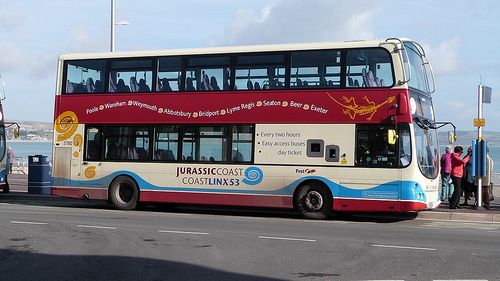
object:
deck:
[63, 59, 396, 91]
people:
[450, 146, 472, 209]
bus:
[0, 75, 14, 191]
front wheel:
[292, 180, 337, 219]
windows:
[62, 48, 396, 93]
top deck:
[56, 37, 432, 115]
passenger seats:
[71, 74, 359, 92]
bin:
[28, 155, 51, 194]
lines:
[11, 219, 437, 251]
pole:
[108, 0, 118, 55]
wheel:
[107, 175, 139, 211]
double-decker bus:
[50, 38, 445, 213]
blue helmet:
[440, 150, 453, 179]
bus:
[50, 37, 458, 220]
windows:
[84, 127, 253, 164]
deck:
[53, 123, 429, 211]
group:
[440, 145, 495, 210]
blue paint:
[52, 167, 427, 200]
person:
[440, 144, 454, 202]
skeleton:
[339, 96, 377, 121]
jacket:
[439, 152, 454, 174]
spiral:
[51, 110, 81, 141]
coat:
[450, 151, 471, 178]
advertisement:
[174, 165, 245, 187]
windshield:
[412, 117, 439, 180]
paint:
[53, 110, 79, 142]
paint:
[70, 133, 83, 149]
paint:
[71, 150, 80, 158]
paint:
[82, 164, 97, 179]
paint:
[323, 88, 396, 120]